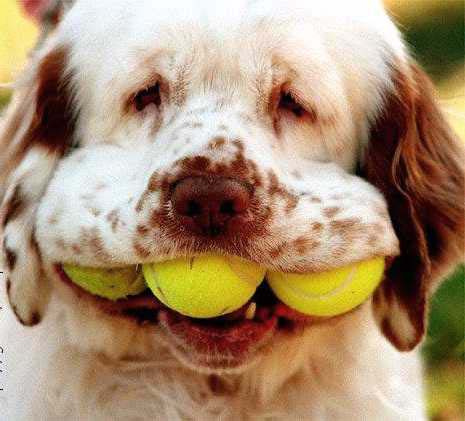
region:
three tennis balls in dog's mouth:
[38, 218, 401, 380]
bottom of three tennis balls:
[47, 223, 387, 331]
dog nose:
[152, 162, 273, 233]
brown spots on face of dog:
[51, 182, 146, 253]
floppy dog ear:
[351, 38, 463, 369]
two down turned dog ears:
[106, 38, 335, 153]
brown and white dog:
[3, 3, 456, 419]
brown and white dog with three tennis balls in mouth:
[5, 1, 460, 419]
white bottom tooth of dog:
[243, 295, 265, 324]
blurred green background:
[415, 263, 464, 416]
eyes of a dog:
[95, 34, 317, 146]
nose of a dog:
[158, 152, 285, 245]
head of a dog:
[3, 8, 460, 353]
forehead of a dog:
[115, 4, 312, 76]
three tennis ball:
[43, 199, 397, 330]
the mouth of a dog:
[43, 115, 416, 389]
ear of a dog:
[365, 84, 454, 373]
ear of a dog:
[0, 68, 95, 313]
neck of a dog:
[61, 319, 354, 419]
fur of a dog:
[51, 346, 155, 411]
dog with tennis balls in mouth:
[1, 0, 464, 420]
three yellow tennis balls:
[56, 256, 385, 318]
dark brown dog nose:
[168, 172, 251, 237]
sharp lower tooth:
[244, 301, 257, 320]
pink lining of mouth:
[69, 270, 314, 351]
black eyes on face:
[126, 73, 312, 124]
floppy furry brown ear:
[370, 60, 463, 354]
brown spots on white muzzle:
[280, 186, 376, 259]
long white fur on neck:
[69, 360, 382, 418]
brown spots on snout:
[166, 103, 257, 151]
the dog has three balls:
[20, 151, 462, 412]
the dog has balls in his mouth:
[39, 229, 463, 369]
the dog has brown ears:
[361, 68, 461, 301]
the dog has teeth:
[140, 282, 299, 407]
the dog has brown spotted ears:
[12, 48, 131, 295]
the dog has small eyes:
[121, 43, 354, 194]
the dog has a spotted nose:
[128, 128, 422, 306]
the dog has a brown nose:
[158, 167, 278, 256]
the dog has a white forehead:
[104, 22, 329, 94]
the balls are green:
[48, 185, 196, 340]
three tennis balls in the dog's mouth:
[59, 256, 385, 315]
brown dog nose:
[172, 177, 248, 232]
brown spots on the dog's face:
[264, 165, 383, 259]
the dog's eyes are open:
[123, 79, 320, 124]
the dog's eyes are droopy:
[115, 72, 324, 121]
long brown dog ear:
[371, 64, 464, 349]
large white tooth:
[242, 300, 255, 321]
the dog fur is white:
[8, 339, 411, 418]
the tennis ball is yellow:
[153, 252, 259, 315]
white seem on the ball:
[281, 266, 358, 298]